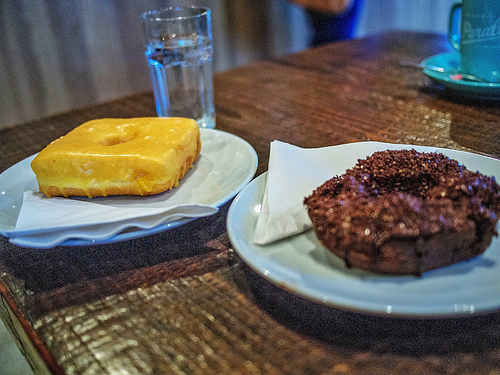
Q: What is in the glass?
A: Water.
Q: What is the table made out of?
A: Wood.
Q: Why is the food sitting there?
A: It was ordered.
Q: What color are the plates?
A: White.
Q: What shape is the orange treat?
A: Square.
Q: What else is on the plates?
A: Napkins.